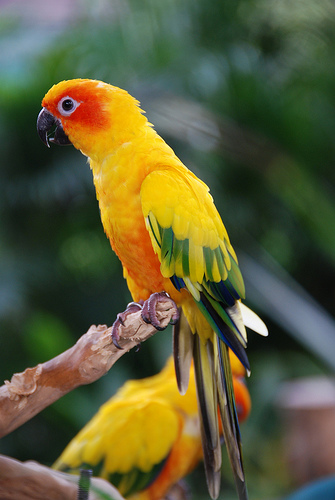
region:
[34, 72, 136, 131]
head of a bird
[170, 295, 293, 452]
tail feathers of bird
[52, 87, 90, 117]
eye of the bird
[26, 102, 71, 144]
beak of the bird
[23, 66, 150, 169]
yellow and red bird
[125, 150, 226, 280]
feather of the bird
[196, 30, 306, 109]
blurry background of photo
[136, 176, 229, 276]
yellow and green feather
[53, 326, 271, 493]
bird behind other bird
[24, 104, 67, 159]
black beak of the bird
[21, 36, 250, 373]
The parrot is standing on the perch.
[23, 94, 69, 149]
The parrot has a black beak.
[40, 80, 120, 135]
The bird has yellow and orange around his face.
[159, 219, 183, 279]
The parrot has green feathers.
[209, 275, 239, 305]
The parrot has blue feathers.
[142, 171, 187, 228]
The bird has yellow feathers.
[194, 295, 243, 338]
The blue feather is next to the green one.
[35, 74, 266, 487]
Another parrot is behind the first parrot.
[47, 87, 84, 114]
The bird's eye is open.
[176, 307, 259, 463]
The feather's cover the bird's face.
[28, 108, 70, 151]
The beak is black.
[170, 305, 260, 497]
The tail feathers are black.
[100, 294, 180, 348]
His feet are black.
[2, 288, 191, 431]
The branch is brown.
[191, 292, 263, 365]
The feathers are blue.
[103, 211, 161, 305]
His belly is orange.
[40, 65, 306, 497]
The bird is colorful.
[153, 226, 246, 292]
The wing is green.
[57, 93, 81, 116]
His eye is black.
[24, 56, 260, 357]
The bird is perched on the branch.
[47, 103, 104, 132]
orange patch near eye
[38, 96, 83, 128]
black and white eye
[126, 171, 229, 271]
green and yellow wing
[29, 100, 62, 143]
bird has black beak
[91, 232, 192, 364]
bird has black talons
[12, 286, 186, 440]
bird on brown branch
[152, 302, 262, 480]
bird has black tail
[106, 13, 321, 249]
green trees behind bird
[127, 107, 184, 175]
bird has yellow back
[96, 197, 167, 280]
orange and yellow breast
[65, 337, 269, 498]
yellow bird on branch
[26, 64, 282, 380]
yellow bird on branch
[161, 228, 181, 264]
green feather of bird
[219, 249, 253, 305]
green feather on bird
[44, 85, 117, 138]
orange feathers near eye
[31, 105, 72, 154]
black beak of bird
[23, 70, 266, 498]
two birds standing on branches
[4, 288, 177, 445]
small branch under bird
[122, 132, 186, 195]
yellow feathers of bird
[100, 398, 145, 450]
yellow feathers of bird